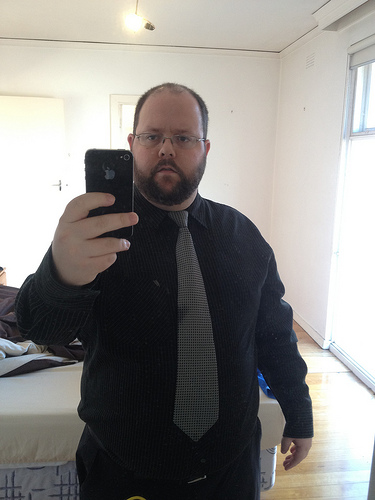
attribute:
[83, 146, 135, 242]
iphone — black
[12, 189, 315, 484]
shirt — black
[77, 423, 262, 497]
pants — black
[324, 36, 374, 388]
window — open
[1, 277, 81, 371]
comforter — blue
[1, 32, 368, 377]
room —  bright"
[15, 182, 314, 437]
shirt — black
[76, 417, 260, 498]
pants — black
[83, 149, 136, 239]
cell phone — black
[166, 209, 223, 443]
tie — checkered, black, grey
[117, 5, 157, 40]
light — on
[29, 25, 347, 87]
wall — white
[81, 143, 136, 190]
phone — Apple, black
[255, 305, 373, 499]
floor — wooden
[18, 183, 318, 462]
shirt — black, striped, button-up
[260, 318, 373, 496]
floor — wood, hardwood, brown, wooden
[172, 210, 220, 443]
tie — gray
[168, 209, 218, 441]
tie — checkered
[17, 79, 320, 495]
man — balding, selfie-taking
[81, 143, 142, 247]
phone —  camera "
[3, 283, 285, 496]
bed — unmade